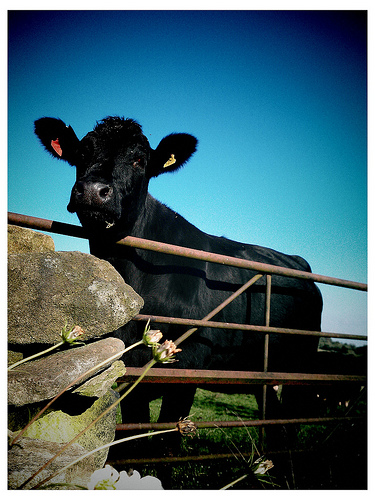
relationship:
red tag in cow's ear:
[49, 140, 63, 156] [31, 114, 79, 166]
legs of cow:
[101, 355, 254, 442] [62, 139, 314, 384]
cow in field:
[62, 139, 314, 384] [95, 331, 354, 484]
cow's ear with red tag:
[31, 114, 79, 166] [49, 140, 63, 156]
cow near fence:
[62, 139, 314, 384] [25, 210, 104, 324]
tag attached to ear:
[160, 152, 178, 169] [150, 131, 199, 178]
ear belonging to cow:
[150, 131, 199, 178] [33, 111, 324, 479]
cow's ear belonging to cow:
[31, 114, 79, 166] [33, 111, 324, 479]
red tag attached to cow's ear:
[49, 140, 63, 156] [31, 114, 79, 166]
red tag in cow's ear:
[49, 140, 63, 156] [31, 118, 79, 165]